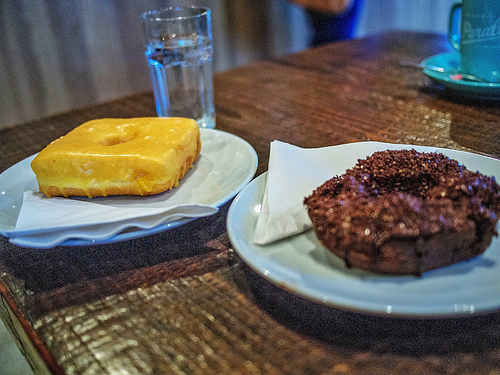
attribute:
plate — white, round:
[225, 144, 495, 322]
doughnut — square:
[37, 109, 201, 191]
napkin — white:
[13, 185, 215, 255]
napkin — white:
[11, 168, 218, 246]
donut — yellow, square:
[300, 135, 498, 272]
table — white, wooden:
[5, 24, 496, 374]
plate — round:
[421, 47, 499, 97]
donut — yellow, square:
[28, 115, 203, 197]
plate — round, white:
[1, 126, 258, 249]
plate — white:
[419, 47, 459, 65]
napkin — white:
[273, 149, 303, 232]